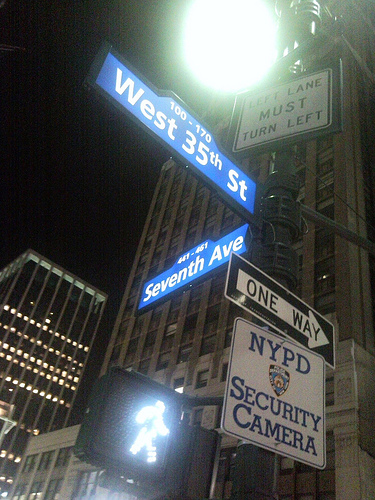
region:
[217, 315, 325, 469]
a square black and white sign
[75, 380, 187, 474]
luminesce blue and white sign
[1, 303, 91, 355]
row of windows in the building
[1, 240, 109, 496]
building in the background with many windows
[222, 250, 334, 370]
black and white direction sign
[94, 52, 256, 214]
street name on a blue and white sign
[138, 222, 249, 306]
blue and white sign with the street name on it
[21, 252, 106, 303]
row of windows on the top floor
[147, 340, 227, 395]
white part of the building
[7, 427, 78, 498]
small white buiding with some windows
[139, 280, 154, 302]
letter s on sign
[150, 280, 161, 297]
letter e on sign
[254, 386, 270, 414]
letter c on sign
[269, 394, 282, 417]
letter u on sign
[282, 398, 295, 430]
letter r on sign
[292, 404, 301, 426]
letter i on sign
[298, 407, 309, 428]
letter t on sign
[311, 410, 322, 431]
letter y on sign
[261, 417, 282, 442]
letter m on sign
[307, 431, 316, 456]
letter a on sign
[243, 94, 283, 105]
word left on sign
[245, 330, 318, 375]
abbrieviation nypd on sign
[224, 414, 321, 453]
word camera on sign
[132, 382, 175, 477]
white symbol to walk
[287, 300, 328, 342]
word way on sign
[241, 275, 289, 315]
word one on sign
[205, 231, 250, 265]
word ave on sign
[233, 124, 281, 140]
word turn on sign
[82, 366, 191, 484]
crossing signal on pole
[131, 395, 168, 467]
walking signal on light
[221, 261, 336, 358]
one way street sign on pole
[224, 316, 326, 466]
white and blue sign on pole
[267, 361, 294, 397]
NYPD logo on sign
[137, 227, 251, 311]
seventh street sign on pole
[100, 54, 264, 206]
west 35th street sign on pole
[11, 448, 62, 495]
windows on the brown building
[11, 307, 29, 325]
lights on in building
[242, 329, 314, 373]
blue print on the sign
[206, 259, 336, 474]
black and whtie street signs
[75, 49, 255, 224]
blue and white street sign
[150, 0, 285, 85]
bright white light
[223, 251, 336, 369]
the sign say's ONE WAY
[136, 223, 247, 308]
the street sign is blue and white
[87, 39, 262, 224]
the street sign says WEST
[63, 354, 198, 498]
a lit up walk sign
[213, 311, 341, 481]
a white and blue sign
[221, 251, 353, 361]
a black and white sign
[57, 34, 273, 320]
a blue and white street sign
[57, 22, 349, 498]
white and blue street sign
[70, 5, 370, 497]
a tall building in the background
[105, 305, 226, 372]
a row of windows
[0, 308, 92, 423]
lights on the building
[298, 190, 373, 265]
pole on the post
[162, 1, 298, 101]
a bright white light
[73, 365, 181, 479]
Walking man sign on the street.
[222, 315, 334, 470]
NYPD security camera sign on a street pole.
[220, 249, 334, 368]
One way sign on a street lamp.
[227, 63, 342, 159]
Left lane must turn left sign on a street lamp.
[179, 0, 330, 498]
A lit up street lamp on the sidewalk.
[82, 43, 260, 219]
A blue street sign on a street lamp.